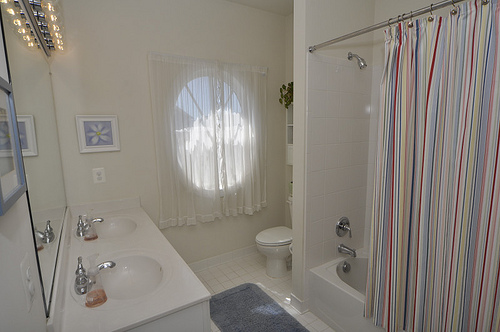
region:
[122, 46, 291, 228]
Unusual round bathroom window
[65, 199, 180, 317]
Double basins vanity sink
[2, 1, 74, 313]
Full length lighted mirror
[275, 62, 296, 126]
Green plant toilet shelving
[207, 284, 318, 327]
Slate blue bath rug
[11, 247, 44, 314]
Electrical double wall socket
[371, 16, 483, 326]
Varigated striped shower curtain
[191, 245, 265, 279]
Small white floor tiles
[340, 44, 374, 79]
Regulation silver shower head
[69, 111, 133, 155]
White framed daisy flower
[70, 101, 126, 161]
white flower painting on wall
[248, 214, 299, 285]
toilet is white and glossy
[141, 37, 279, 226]
Rectangular white curtain covering an oval window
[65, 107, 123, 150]
Framed painting of a daisy on the wall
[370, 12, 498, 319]
Multicolored striped shower curtain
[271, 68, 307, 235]
What cabinet over toilet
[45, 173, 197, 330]
Two sinks next to each other on a double vanity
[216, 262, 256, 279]
Floor with white square tiles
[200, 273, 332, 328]
Grey bathroom mat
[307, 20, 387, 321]
Combined shower and bathtub with silver fixtures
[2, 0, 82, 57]
Turned on row of lights above a mirror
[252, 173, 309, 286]
White porcelain toilet with lid down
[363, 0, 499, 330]
striped curtain is hanging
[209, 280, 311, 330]
blue bathmat on the floor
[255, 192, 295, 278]
white toilet behind bathmat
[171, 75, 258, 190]
circular window behind toilet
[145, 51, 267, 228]
white curtain is hanging over window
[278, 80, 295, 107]
green plant over toilet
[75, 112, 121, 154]
picture of flower on wall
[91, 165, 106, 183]
white outlet under picture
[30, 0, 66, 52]
exposed light bulbs are on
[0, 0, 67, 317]
mirror under the light bulbs